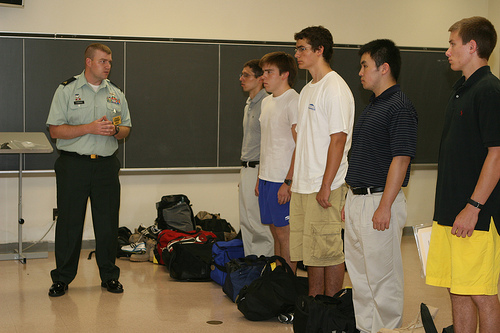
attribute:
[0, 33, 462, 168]
chalkboard — long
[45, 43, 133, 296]
officer — standing, in the room, police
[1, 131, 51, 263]
podium — moveable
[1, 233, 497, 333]
floor — brown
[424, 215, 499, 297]
shorts — yellow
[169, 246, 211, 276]
duffle bag — black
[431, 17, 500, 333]
recruit — timid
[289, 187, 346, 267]
shorts — brown, khaki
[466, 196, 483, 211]
band — black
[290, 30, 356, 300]
man — standing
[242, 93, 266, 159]
shirt — green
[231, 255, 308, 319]
bag — red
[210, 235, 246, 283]
bag — blue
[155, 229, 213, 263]
bag — red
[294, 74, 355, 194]
shirt — white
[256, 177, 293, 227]
shorts — blue